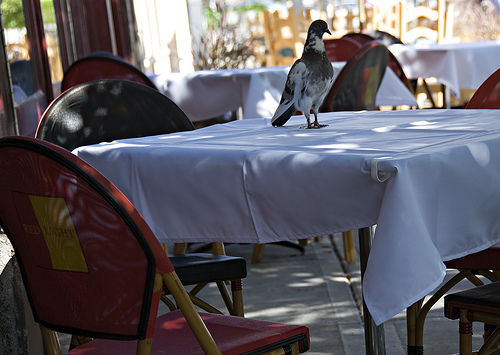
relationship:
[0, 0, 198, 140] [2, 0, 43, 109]
building has window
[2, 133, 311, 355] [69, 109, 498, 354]
chair near table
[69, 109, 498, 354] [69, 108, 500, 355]
table has table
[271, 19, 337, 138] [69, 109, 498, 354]
bird on table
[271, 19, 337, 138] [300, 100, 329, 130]
bird has feet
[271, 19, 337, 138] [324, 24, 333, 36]
bird has beak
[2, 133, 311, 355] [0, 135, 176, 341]
chair has back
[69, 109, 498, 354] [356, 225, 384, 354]
table has leg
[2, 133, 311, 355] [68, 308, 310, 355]
chair has seat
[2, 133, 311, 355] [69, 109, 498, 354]
chair next to table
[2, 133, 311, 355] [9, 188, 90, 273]
chair has design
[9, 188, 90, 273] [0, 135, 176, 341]
design on back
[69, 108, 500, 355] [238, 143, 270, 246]
table has fold line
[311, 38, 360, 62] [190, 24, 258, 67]
chair near bush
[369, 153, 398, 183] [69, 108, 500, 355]
bracket holding table